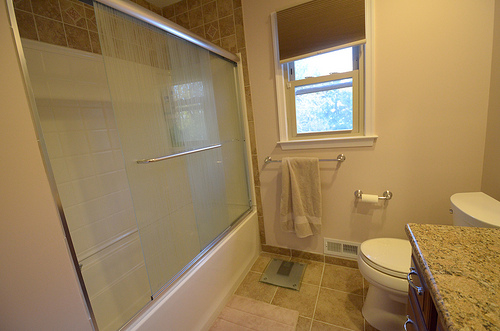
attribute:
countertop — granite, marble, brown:
[405, 220, 499, 330]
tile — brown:
[217, 14, 235, 39]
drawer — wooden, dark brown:
[409, 256, 434, 330]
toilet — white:
[356, 191, 498, 330]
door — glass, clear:
[95, 0, 233, 302]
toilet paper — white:
[360, 193, 377, 204]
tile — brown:
[235, 269, 278, 302]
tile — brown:
[270, 283, 321, 321]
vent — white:
[323, 238, 359, 261]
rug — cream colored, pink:
[201, 293, 301, 330]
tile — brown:
[247, 252, 292, 273]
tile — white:
[43, 48, 75, 77]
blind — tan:
[276, 1, 367, 66]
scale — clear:
[258, 257, 306, 291]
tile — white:
[21, 45, 47, 76]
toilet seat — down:
[359, 238, 413, 280]